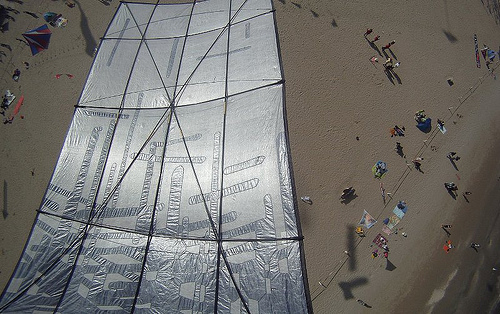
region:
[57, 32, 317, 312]
large kite on the beach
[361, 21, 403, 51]
people standing on the beach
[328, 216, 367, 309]
shadows on the beach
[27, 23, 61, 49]
tent on the beach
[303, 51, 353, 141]
dry sand at the beach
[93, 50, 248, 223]
large silver kite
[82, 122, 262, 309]
lines drawn on the large kite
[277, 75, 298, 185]
edge of the kite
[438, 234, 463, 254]
orange blanket on the beach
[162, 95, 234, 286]
long pole for the kite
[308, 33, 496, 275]
people on the beach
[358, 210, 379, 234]
kite on the beach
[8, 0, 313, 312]
kite in the air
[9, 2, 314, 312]
design on the kite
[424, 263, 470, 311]
wave on the shore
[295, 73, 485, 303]
rut in the sand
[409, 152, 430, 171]
person on the beach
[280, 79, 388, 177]
footprints in the sand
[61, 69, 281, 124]
strut of the kite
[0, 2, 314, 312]
Large poster on the beach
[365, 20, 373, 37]
Person standing on the beach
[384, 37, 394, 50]
Person standing on the beach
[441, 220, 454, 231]
Person standing on the beach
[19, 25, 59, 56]
Red, white and blue umbrella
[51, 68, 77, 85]
Red flags in the air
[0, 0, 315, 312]
White and black sign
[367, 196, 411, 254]
Towels on the beach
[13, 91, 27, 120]
Orange object on the beach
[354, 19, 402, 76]
people on the floor throwing kites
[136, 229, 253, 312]
black grey polythene paer suspended in the atmospher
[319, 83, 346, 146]
the floor is brown in color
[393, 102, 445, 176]
kites suspended in the atmosphere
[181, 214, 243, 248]
the ropes are black in color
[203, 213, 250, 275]
the ropes are intersecting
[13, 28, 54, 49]
an umbrella in the air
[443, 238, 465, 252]
an orange cloth on the ground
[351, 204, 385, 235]
a colored kite in the air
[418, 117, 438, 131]
a blue cloth on the ground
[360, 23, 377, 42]
person standing on a sandy beach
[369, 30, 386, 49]
person standing on a sandy beach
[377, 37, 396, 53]
person standing on a sandy beach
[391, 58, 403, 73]
person standing on a sandy beach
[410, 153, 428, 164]
person standing on a sandy beach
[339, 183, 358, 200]
person standing on a sandy beach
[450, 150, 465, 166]
person standing on a sandy beach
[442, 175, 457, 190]
person standing on a sandy beach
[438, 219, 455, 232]
person standing on a sandy beach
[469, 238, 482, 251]
person standing on a sandy beach